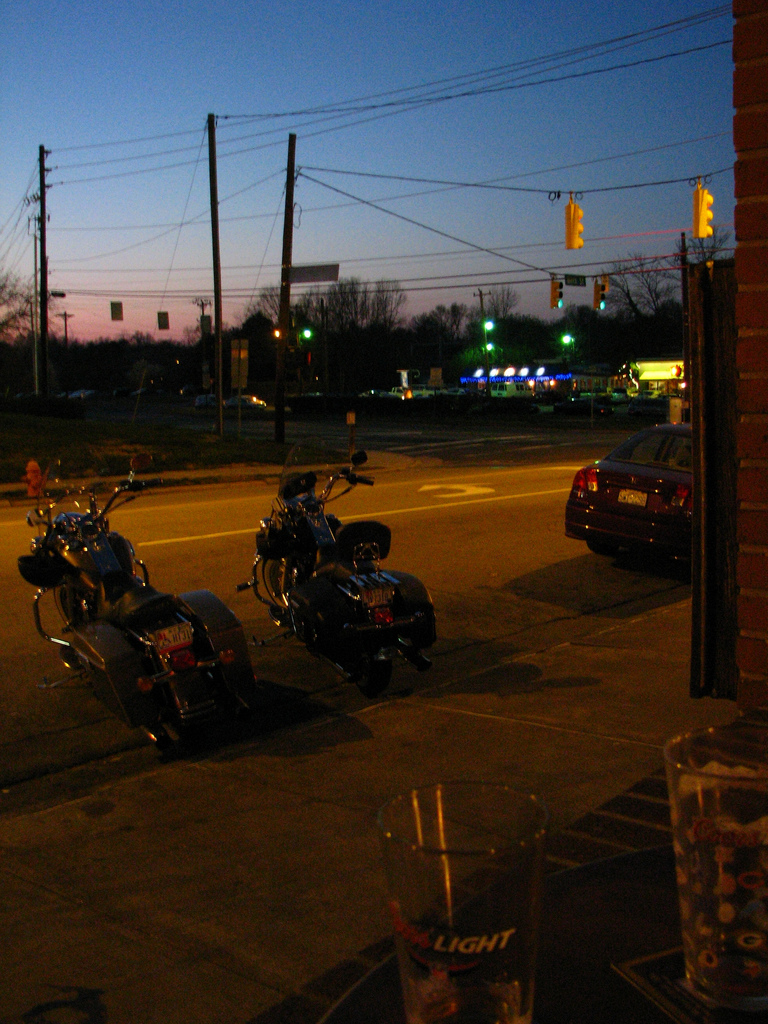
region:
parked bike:
[36, 461, 252, 725]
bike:
[260, 452, 437, 679]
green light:
[299, 312, 326, 362]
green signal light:
[460, 295, 519, 378]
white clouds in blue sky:
[89, 189, 138, 238]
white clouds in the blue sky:
[400, 186, 432, 230]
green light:
[276, 299, 324, 354]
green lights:
[471, 312, 513, 367]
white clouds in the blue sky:
[141, 242, 170, 280]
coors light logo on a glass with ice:
[349, 897, 527, 959]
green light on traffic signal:
[474, 316, 499, 340]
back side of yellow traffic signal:
[553, 192, 595, 260]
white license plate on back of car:
[604, 479, 662, 514]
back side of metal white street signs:
[231, 327, 262, 402]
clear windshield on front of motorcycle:
[271, 437, 344, 500]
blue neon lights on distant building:
[464, 360, 570, 392]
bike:
[1, 472, 256, 771]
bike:
[221, 435, 454, 695]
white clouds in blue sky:
[69, 146, 109, 186]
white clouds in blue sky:
[77, 202, 106, 231]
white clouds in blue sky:
[572, 80, 671, 178]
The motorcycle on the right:
[20, 444, 272, 757]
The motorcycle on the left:
[235, 449, 457, 702]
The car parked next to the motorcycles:
[557, 420, 697, 594]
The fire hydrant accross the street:
[16, 455, 44, 498]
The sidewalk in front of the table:
[2, 592, 721, 1023]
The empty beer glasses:
[364, 720, 763, 1021]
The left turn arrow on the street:
[419, 471, 496, 506]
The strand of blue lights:
[456, 372, 584, 389]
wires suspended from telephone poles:
[0, 11, 729, 401]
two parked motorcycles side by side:
[17, 427, 437, 755]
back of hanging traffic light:
[686, 177, 716, 239]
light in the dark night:
[294, 321, 312, 339]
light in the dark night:
[269, 321, 277, 342]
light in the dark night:
[480, 315, 493, 338]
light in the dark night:
[479, 340, 494, 360]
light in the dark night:
[551, 325, 571, 349]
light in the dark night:
[594, 296, 604, 316]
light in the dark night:
[472, 365, 484, 375]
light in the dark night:
[486, 365, 502, 379]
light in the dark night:
[501, 364, 516, 383]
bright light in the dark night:
[299, 319, 326, 354]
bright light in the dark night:
[270, 324, 277, 341]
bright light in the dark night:
[481, 339, 491, 354]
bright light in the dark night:
[556, 326, 569, 344]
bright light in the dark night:
[552, 292, 564, 304]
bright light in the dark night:
[595, 298, 604, 307]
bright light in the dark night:
[471, 364, 486, 378]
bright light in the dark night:
[501, 364, 516, 380]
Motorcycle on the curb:
[243, 429, 453, 689]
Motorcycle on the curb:
[20, 452, 274, 783]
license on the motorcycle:
[357, 578, 399, 614]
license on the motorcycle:
[352, 574, 399, 609]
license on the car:
[608, 487, 655, 513]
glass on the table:
[375, 783, 567, 1019]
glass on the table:
[661, 709, 765, 1016]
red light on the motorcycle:
[157, 642, 206, 683]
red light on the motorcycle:
[367, 602, 395, 625]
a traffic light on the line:
[552, 176, 600, 246]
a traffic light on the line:
[682, 166, 758, 258]